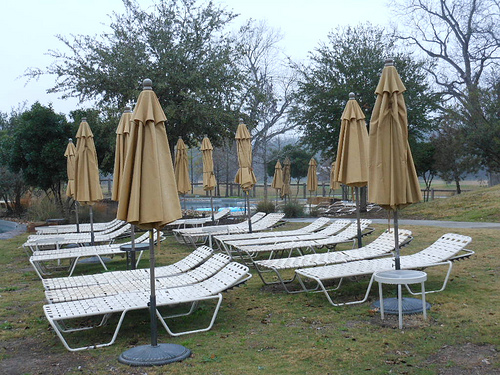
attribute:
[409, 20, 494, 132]
tree — bare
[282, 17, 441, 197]
tree — leafless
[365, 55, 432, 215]
umbrella — beige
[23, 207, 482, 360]
lounges — rounded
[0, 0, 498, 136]
sky — dull 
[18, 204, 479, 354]
chairs — white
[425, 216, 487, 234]
walkway — grey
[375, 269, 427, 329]
table — white , small 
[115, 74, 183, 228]
umbrella — brown 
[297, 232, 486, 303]
chairs — lounge 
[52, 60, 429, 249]
folded umbreelas — laid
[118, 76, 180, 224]
umbrella — closed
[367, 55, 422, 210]
umbrella — closed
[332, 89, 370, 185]
umbrella — closed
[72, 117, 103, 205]
umbrella — closed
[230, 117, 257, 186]
umbrella — closed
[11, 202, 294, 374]
chairs — lounge 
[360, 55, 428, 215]
umbrella — brown 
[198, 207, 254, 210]
pool — blue 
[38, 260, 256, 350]
chair — lounge 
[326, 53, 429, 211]
umbrellas — brown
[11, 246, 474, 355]
grass — browning